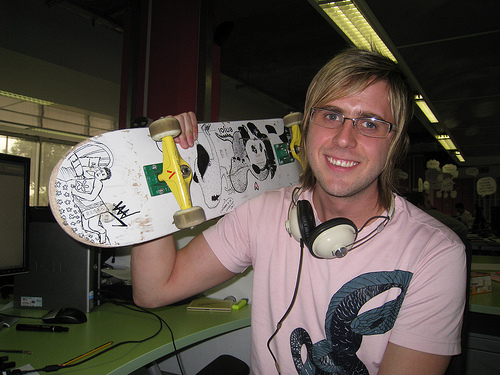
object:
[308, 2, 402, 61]
lights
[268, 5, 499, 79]
ceiling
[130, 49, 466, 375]
man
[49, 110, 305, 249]
skateboard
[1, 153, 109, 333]
computer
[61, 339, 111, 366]
pencil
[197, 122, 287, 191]
doodles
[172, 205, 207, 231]
wheels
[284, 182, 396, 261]
headphones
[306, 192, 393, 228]
neck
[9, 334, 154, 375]
cables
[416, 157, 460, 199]
drawings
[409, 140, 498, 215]
wall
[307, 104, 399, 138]
glasses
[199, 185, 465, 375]
shirt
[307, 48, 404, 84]
hair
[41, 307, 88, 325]
mouse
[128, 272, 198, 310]
elbow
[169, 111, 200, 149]
hand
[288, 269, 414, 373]
snake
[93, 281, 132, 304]
case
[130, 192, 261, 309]
arm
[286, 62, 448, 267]
skateboarder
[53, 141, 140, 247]
drawings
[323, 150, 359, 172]
mouth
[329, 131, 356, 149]
nose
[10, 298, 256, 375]
desk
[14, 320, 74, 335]
marker